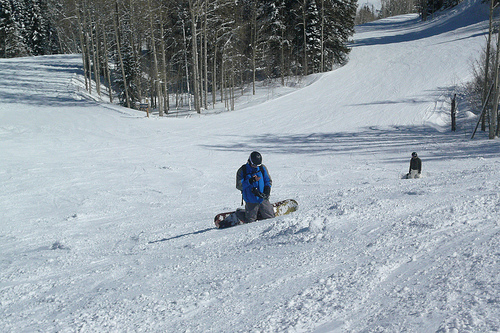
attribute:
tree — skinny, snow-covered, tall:
[72, 16, 99, 91]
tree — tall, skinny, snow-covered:
[481, 10, 495, 132]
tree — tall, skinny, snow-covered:
[143, 25, 177, 110]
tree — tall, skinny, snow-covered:
[183, 23, 206, 107]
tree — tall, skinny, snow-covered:
[288, 4, 323, 69]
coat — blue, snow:
[217, 173, 278, 218]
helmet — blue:
[250, 153, 260, 164]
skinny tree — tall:
[200, 2, 213, 110]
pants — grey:
[238, 198, 277, 221]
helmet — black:
[246, 148, 265, 170]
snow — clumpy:
[283, 212, 340, 254]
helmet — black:
[247, 152, 264, 166]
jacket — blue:
[232, 166, 272, 203]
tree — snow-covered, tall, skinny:
[188, 30, 199, 115]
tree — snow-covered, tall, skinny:
[318, 5, 324, 70]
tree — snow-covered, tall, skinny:
[279, 21, 285, 89]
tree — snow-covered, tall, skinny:
[88, 37, 103, 94]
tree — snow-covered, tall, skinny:
[248, 6, 260, 94]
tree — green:
[299, 0, 359, 73]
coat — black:
[405, 155, 425, 174]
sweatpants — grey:
[240, 199, 275, 221]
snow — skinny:
[256, 35, 270, 70]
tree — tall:
[237, 2, 277, 94]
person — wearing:
[201, 117, 282, 229]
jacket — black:
[409, 157, 421, 168]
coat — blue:
[236, 165, 271, 203]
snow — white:
[43, 155, 140, 260]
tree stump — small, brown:
[448, 93, 462, 133]